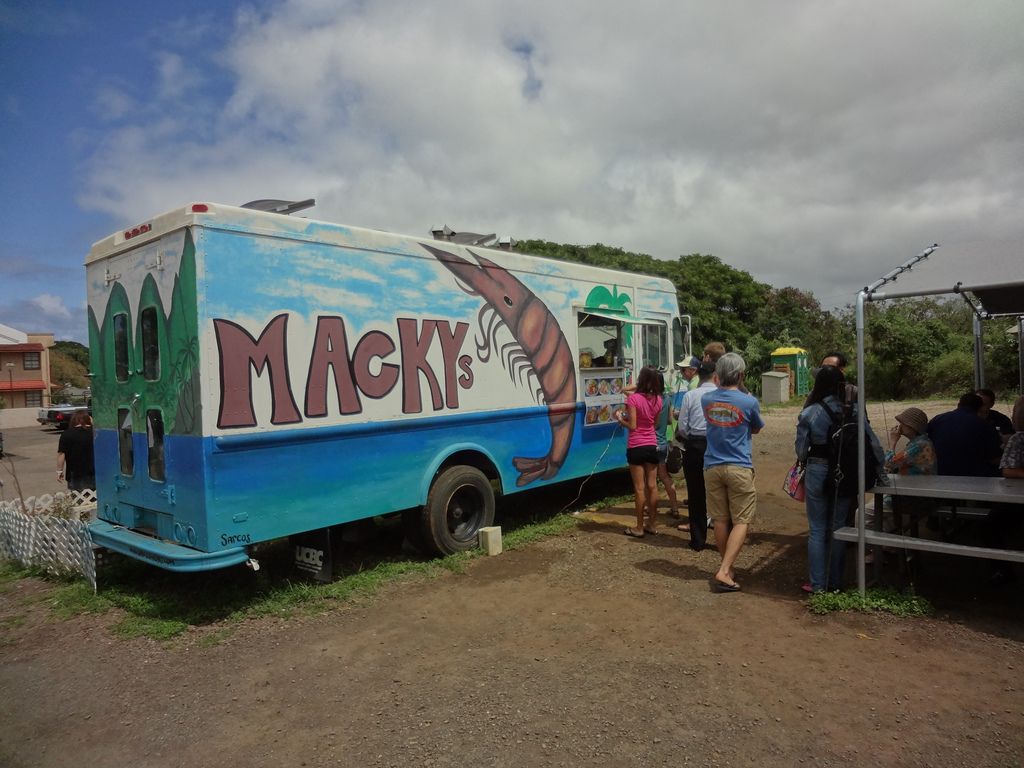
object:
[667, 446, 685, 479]
tire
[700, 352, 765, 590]
man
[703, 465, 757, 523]
shorts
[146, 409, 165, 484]
window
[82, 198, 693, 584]
vehicle